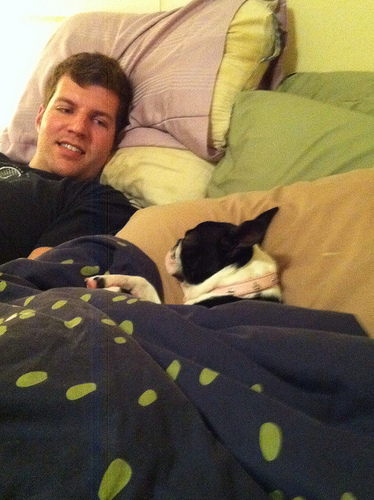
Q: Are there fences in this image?
A: No, there are no fences.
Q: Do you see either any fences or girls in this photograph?
A: No, there are no fences or girls.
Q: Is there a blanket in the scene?
A: Yes, there is a blanket.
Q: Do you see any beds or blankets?
A: Yes, there is a blanket.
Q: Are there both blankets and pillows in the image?
A: Yes, there are both a blanket and a pillow.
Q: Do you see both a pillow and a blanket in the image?
A: Yes, there are both a blanket and a pillow.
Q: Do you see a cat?
A: No, there are no cats.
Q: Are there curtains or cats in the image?
A: No, there are no cats or curtains.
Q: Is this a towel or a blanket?
A: This is a blanket.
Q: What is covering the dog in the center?
A: The blanket is covering the dog.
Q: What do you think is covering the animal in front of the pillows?
A: The blanket is covering the dog.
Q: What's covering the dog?
A: The blanket is covering the dog.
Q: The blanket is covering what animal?
A: The blanket is covering the dog.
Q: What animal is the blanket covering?
A: The blanket is covering the dog.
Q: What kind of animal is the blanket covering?
A: The blanket is covering the dog.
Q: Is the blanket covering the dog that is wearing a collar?
A: Yes, the blanket is covering the dog.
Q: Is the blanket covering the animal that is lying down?
A: Yes, the blanket is covering the dog.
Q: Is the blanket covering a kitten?
A: No, the blanket is covering the dog.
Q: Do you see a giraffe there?
A: No, there are no giraffes.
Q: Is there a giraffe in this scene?
A: No, there are no giraffes.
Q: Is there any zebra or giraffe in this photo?
A: No, there are no giraffes or zebras.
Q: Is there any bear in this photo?
A: No, there are no bears.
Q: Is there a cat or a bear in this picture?
A: No, there are no bears or cats.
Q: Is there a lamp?
A: No, there are no lamps.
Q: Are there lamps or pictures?
A: No, there are no lamps or pictures.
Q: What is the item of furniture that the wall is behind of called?
A: The piece of furniture is a bed.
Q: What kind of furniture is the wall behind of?
A: The wall is behind the bed.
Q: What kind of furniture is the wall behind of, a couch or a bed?
A: The wall is behind a bed.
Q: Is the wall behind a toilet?
A: No, the wall is behind a bed.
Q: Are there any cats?
A: No, there are no cats.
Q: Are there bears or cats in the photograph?
A: No, there are no cats or bears.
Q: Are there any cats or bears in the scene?
A: No, there are no cats or bears.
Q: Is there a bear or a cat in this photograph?
A: No, there are no cats or bears.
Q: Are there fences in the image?
A: No, there are no fences.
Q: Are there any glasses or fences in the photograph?
A: No, there are no fences or glasses.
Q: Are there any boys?
A: No, there are no boys.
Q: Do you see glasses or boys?
A: No, there are no boys or glasses.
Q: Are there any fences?
A: No, there are no fences.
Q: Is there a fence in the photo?
A: No, there are no fences.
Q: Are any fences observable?
A: No, there are no fences.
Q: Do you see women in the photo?
A: No, there are no women.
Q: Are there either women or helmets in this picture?
A: No, there are no women or helmets.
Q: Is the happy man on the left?
A: Yes, the man is on the left of the image.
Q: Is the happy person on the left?
A: Yes, the man is on the left of the image.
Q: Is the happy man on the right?
A: No, the man is on the left of the image.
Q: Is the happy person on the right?
A: No, the man is on the left of the image.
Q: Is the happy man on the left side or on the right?
A: The man is on the left of the image.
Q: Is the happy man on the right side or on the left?
A: The man is on the left of the image.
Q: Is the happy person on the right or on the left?
A: The man is on the left of the image.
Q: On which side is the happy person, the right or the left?
A: The man is on the left of the image.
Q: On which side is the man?
A: The man is on the left of the image.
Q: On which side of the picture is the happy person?
A: The man is on the left of the image.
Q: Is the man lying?
A: Yes, the man is lying.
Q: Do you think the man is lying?
A: Yes, the man is lying.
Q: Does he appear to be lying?
A: Yes, the man is lying.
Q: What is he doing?
A: The man is lying.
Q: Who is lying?
A: The man is lying.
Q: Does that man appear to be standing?
A: No, the man is lying.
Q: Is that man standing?
A: No, the man is lying.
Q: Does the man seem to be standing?
A: No, the man is lying.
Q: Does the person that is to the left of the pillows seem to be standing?
A: No, the man is lying.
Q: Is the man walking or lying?
A: The man is lying.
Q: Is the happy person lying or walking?
A: The man is lying.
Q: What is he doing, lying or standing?
A: The man is lying.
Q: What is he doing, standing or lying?
A: The man is lying.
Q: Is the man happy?
A: Yes, the man is happy.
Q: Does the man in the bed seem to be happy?
A: Yes, the man is happy.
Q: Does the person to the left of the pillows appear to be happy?
A: Yes, the man is happy.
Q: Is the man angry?
A: No, the man is happy.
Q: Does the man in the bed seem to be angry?
A: No, the man is happy.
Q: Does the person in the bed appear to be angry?
A: No, the man is happy.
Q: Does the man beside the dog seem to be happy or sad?
A: The man is happy.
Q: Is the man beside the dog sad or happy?
A: The man is happy.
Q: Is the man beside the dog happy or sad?
A: The man is happy.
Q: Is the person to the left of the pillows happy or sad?
A: The man is happy.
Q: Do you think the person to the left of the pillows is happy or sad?
A: The man is happy.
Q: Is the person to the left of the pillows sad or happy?
A: The man is happy.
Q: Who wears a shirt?
A: The man wears a shirt.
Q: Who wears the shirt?
A: The man wears a shirt.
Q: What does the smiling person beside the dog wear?
A: The man wears a shirt.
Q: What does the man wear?
A: The man wears a shirt.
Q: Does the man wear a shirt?
A: Yes, the man wears a shirt.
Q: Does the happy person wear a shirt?
A: Yes, the man wears a shirt.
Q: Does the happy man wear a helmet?
A: No, the man wears a shirt.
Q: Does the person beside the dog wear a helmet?
A: No, the man wears a shirt.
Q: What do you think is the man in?
A: The man is in the bed.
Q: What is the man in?
A: The man is in the bed.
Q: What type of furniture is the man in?
A: The man is in the bed.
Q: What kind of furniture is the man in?
A: The man is in the bed.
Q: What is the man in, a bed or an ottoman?
A: The man is in a bed.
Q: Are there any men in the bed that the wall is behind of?
A: Yes, there is a man in the bed.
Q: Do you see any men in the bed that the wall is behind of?
A: Yes, there is a man in the bed.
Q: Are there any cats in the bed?
A: No, there is a man in the bed.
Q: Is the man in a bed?
A: Yes, the man is in a bed.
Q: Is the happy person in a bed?
A: Yes, the man is in a bed.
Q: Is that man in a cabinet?
A: No, the man is in a bed.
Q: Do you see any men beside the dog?
A: Yes, there is a man beside the dog.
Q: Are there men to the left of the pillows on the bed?
A: Yes, there is a man to the left of the pillows.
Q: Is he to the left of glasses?
A: No, the man is to the left of the pillows.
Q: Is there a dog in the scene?
A: Yes, there is a dog.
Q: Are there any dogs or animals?
A: Yes, there is a dog.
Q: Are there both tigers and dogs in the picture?
A: No, there is a dog but no tigers.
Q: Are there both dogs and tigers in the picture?
A: No, there is a dog but no tigers.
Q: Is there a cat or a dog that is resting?
A: Yes, the dog is resting.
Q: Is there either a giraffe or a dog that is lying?
A: Yes, the dog is lying.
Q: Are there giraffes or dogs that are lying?
A: Yes, the dog is lying.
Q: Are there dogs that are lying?
A: Yes, there is a dog that is lying.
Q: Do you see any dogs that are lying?
A: Yes, there is a dog that is lying.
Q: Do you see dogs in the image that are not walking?
A: Yes, there is a dog that is lying .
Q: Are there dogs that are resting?
A: Yes, there is a dog that is resting.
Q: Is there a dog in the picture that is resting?
A: Yes, there is a dog that is resting.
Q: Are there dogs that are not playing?
A: Yes, there is a dog that is resting.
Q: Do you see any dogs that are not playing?
A: Yes, there is a dog that is resting .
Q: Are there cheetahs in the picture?
A: No, there are no cheetahs.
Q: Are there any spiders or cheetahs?
A: No, there are no cheetahs or spiders.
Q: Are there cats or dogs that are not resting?
A: No, there is a dog but it is resting.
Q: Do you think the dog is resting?
A: Yes, the dog is resting.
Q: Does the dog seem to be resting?
A: Yes, the dog is resting.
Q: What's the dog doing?
A: The dog is resting.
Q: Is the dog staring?
A: No, the dog is resting.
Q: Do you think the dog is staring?
A: No, the dog is resting.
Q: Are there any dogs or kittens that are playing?
A: No, there is a dog but it is resting.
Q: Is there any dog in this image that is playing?
A: No, there is a dog but it is resting.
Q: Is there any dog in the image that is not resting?
A: No, there is a dog but it is resting.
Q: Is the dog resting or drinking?
A: The dog is resting.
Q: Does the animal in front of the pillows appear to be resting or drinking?
A: The dog is resting.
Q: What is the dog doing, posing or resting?
A: The dog is resting.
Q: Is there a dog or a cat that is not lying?
A: No, there is a dog but it is lying.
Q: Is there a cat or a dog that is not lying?
A: No, there is a dog but it is lying.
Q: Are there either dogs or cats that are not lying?
A: No, there is a dog but it is lying.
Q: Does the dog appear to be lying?
A: Yes, the dog is lying.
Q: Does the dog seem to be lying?
A: Yes, the dog is lying.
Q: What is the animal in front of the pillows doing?
A: The dog is lying.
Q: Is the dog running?
A: No, the dog is lying.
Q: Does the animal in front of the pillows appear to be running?
A: No, the dog is lying.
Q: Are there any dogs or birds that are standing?
A: No, there is a dog but it is lying.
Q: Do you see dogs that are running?
A: No, there is a dog but it is lying.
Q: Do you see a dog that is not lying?
A: No, there is a dog but it is lying.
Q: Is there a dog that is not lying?
A: No, there is a dog but it is lying.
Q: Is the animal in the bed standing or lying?
A: The dog is lying.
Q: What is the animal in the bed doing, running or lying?
A: The dog is lying.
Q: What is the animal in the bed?
A: The animal is a dog.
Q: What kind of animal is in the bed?
A: The animal is a dog.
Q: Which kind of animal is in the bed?
A: The animal is a dog.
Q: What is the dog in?
A: The dog is in the bed.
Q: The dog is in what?
A: The dog is in the bed.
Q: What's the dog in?
A: The dog is in the bed.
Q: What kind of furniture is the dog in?
A: The dog is in the bed.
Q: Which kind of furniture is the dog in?
A: The dog is in the bed.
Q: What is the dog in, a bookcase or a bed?
A: The dog is in a bed.